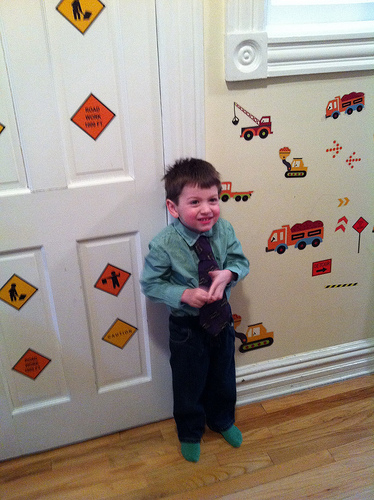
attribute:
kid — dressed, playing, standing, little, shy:
[140, 158, 250, 463]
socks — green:
[180, 428, 241, 461]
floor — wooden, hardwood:
[2, 373, 374, 496]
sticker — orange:
[69, 93, 116, 140]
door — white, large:
[3, 3, 174, 457]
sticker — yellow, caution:
[102, 318, 138, 350]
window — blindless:
[267, 4, 373, 36]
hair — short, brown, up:
[162, 158, 224, 203]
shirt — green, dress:
[141, 221, 249, 314]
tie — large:
[194, 238, 235, 331]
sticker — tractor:
[265, 218, 323, 253]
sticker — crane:
[229, 102, 274, 140]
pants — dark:
[166, 313, 238, 440]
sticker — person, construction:
[92, 264, 131, 296]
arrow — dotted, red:
[326, 140, 343, 159]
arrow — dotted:
[345, 151, 361, 167]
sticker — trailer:
[281, 144, 309, 178]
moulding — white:
[221, 7, 371, 83]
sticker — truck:
[219, 178, 255, 203]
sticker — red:
[352, 216, 368, 253]